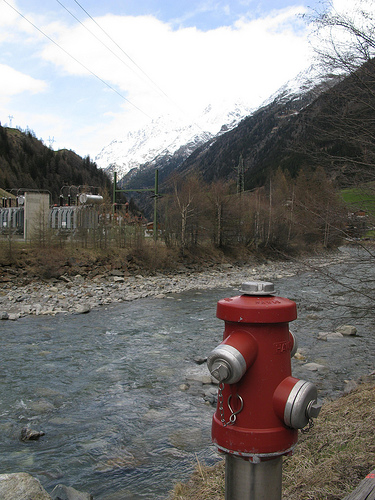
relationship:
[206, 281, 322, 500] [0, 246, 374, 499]
fire hydrant next to a creek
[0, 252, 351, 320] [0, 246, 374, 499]
rocky area next to creek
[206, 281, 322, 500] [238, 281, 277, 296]
fire hydrant has a cap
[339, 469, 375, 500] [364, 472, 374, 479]
wood has a marking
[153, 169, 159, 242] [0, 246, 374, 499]
post behind creek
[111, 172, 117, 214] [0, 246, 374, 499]
post behind creek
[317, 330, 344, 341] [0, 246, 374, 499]
rock sticking out of creek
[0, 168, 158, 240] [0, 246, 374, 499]
power station next to creek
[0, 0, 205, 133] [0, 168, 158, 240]
power lines are over power station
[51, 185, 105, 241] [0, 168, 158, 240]
transformer at power station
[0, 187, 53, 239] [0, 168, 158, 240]
transformer at power station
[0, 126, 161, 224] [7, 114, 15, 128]
hillside has an electrical pole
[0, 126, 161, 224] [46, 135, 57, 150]
hillside has an electrical pole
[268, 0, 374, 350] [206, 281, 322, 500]
tree near fire hydrant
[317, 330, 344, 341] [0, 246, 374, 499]
rock protruding from creek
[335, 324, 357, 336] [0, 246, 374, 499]
rock protruding from creek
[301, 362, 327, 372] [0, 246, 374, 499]
rock protruding from creek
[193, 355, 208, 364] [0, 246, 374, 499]
rock protruding from creek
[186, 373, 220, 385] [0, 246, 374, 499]
rock protruding from creek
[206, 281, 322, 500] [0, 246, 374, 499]
fire hydrant next to creek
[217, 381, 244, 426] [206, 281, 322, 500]
chain hanging from fire hydrant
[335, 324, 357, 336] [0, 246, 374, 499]
rock in creek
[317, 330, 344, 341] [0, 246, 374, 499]
rock in creek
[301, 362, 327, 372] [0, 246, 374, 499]
rock in creek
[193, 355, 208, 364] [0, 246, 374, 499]
rock in creek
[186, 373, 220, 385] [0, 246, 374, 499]
rock in creek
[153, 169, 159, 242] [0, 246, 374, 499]
post next to creek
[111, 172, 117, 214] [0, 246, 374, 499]
post next to creek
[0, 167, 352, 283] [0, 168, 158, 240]
wooded area covering power station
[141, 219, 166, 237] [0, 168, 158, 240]
house behind power station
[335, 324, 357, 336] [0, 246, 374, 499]
rock sticking out of creek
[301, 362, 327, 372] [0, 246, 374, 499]
rock sticking out of creek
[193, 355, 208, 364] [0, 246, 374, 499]
rock sticking out of creek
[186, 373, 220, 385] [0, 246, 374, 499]
rock sticking out of creek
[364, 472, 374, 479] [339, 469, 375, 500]
marking on wood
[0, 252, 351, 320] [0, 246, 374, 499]
rocky area shore of creek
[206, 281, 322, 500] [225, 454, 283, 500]
fire hydrant has a post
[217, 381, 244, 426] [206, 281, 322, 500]
chain on fire hydrant